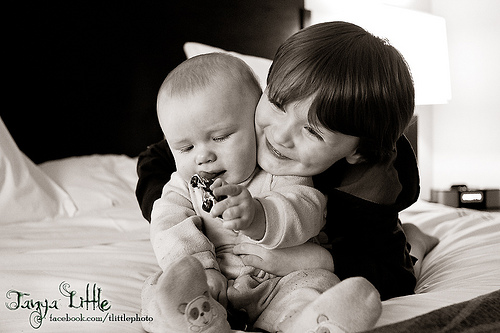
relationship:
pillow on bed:
[184, 44, 281, 94] [0, 1, 499, 333]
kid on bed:
[138, 24, 420, 300] [0, 1, 499, 333]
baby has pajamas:
[152, 51, 383, 333] [144, 171, 382, 331]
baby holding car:
[152, 51, 383, 333] [193, 172, 227, 212]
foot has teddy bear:
[152, 262, 228, 332] [182, 294, 219, 332]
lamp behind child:
[319, 2, 452, 105] [138, 24, 420, 300]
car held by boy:
[193, 172, 227, 212] [152, 51, 383, 333]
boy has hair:
[152, 51, 383, 333] [152, 51, 263, 101]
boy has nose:
[152, 51, 383, 333] [196, 149, 217, 164]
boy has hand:
[152, 51, 383, 333] [211, 184, 256, 229]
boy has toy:
[152, 51, 383, 333] [193, 172, 227, 212]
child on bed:
[138, 24, 420, 300] [0, 1, 499, 333]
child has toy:
[138, 24, 420, 300] [193, 172, 227, 212]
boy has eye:
[152, 51, 383, 333] [214, 133, 228, 142]